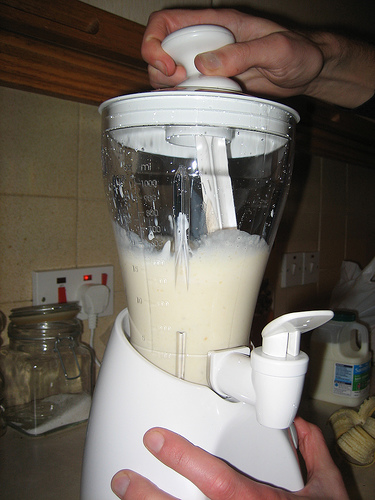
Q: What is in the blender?
A: White liquid.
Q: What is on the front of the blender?
A: Spout.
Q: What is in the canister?
A: Sugar.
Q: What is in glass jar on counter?
A: Sugar.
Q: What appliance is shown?
A: Blender.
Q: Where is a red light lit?
A: Outlet.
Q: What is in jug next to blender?
A: Milk.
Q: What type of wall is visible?
A: Tile.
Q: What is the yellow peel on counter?
A: Banana.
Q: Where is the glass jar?
A: Behind the blender.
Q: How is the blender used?
A: Plunger.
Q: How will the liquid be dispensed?
A: Spout on front.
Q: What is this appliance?
A: Juicing blender.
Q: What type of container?
A: Clear glass.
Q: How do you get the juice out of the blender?
A: A pouring nozzle.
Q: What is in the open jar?
A: Sugar.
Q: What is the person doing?
A: Making a snack.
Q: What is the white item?
A: A mixer.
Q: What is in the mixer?
A: Smoothies.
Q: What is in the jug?
A: Milk.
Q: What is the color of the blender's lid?
A: White.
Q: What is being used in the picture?
A: A blender.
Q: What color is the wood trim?
A: Brown.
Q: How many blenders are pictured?
A: One.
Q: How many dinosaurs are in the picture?
A: Zero.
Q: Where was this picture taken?
A: In a kitchen.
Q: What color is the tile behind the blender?
A: Beige.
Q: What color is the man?
A: White.